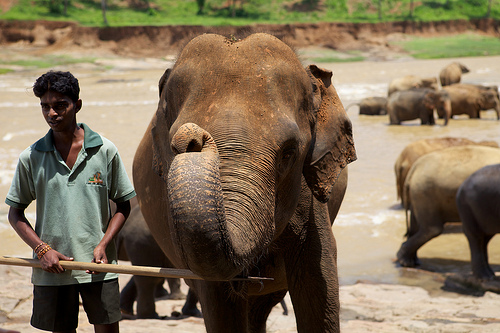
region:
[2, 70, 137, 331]
An Indian guy in a green shirt and black shorts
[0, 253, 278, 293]
A pole used to control Elephants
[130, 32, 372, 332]
An Elephant with their trunk up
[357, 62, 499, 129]
Many Elephants in a river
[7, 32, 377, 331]
A man controlling an Elephant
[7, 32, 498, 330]
A guy with a bunch of Elephants at a river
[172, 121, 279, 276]
the curled trunk of an elephant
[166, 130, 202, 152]
the nostrils of an elephant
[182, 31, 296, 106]
the bumpy forehead of an elephant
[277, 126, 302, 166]
the darkened left eye of an elephant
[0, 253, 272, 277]
a wooden training stick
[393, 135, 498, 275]
the sides of three elephants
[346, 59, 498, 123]
several elephants standing in river water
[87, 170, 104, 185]
an emblem on the front of a man's shirt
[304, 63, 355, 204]
the floppy ear of an elephant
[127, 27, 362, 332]
large brown elephant with curled trunk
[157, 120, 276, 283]
brown curled elephant trunk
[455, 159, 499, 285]
back end of black elephant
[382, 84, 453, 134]
distant elephant standing in water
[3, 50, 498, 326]
area of water behind large elephant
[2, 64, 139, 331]
man with black hair holding stick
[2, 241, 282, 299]
long stick in man's hands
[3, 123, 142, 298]
men's green polo style shirt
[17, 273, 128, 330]
men's green casual shorts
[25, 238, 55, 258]
bracelets on right wrist of man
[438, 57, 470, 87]
elephant in the water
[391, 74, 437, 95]
elephant in the water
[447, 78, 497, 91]
elephant in the water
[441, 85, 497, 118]
elephant in the water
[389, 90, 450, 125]
elephant in the water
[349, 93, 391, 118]
elephant in the water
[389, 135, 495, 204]
elephant in the water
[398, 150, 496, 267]
elephant in the water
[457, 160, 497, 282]
elephant in the water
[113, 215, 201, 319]
elephant in the water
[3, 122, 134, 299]
A light green shirt on a boy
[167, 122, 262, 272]
An elephant's curved trunk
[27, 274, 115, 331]
Black shorts on a boy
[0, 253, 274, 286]
A light brown pole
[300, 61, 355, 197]
A dirt encrusted ear on an elephant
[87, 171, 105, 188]
A logo on a shirt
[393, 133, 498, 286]
Three elephants in water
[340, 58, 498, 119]
A group of elephants in water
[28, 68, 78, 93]
Black hair on a man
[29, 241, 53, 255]
Bracelets on a man's wrist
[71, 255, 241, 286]
the stick is tan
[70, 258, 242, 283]
the stick is wooden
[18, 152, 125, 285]
the shirt is green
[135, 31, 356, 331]
a small grey elephant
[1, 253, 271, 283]
a long wooden stick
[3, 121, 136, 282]
a green polo shirt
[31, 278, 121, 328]
a pair of black shorts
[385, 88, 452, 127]
an elephant standing in water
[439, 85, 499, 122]
an elephant standing in water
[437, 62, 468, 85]
an elephant standing in water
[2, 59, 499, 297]
a muddy river of water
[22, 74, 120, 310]
A man in a green shirt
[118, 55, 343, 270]
a elephantStanding next to a man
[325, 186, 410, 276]
A very muddy river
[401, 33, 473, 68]
A patch of green grass in the background